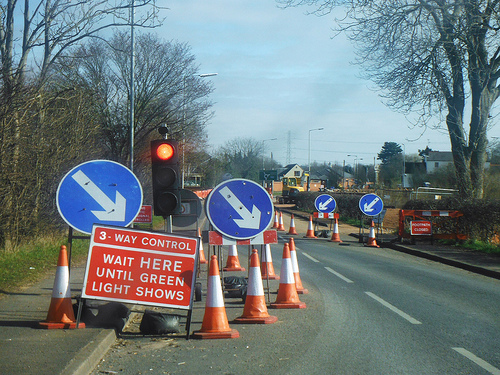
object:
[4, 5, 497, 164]
sky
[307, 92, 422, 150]
clouds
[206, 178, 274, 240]
sign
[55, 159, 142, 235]
sign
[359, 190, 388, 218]
sign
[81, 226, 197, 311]
sign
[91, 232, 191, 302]
writing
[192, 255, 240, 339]
cone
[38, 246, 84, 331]
cone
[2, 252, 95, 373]
sidewalk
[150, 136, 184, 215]
street light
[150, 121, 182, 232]
pole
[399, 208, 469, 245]
barricade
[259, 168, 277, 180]
traffic sign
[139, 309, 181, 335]
bag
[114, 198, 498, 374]
street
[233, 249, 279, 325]
cone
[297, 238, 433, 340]
line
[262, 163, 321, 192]
house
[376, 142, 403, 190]
tree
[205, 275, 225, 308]
stripe